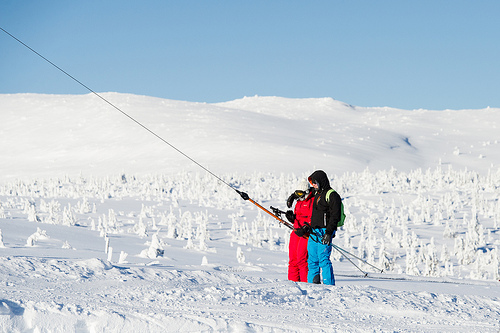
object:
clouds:
[1, 0, 499, 110]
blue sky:
[0, 0, 500, 110]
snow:
[0, 91, 499, 199]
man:
[284, 175, 315, 283]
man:
[306, 170, 347, 285]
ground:
[0, 178, 499, 333]